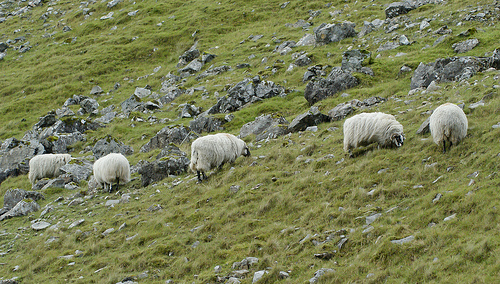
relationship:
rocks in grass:
[22, 18, 500, 181] [0, 0, 499, 282]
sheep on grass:
[25, 82, 475, 187] [0, 0, 499, 282]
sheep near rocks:
[25, 82, 475, 187] [22, 18, 500, 181]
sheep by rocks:
[25, 82, 475, 187] [22, 18, 500, 181]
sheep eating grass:
[25, 82, 475, 187] [0, 0, 499, 282]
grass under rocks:
[0, 0, 499, 282] [22, 18, 500, 181]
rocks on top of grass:
[22, 18, 500, 181] [0, 0, 499, 282]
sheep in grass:
[25, 82, 475, 187] [0, 0, 499, 282]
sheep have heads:
[25, 82, 475, 187] [229, 136, 409, 159]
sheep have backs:
[25, 82, 475, 187] [15, 120, 468, 166]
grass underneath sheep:
[0, 0, 499, 282] [25, 82, 475, 187]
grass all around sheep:
[0, 0, 499, 282] [25, 82, 475, 187]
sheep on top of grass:
[25, 82, 475, 187] [0, 0, 499, 282]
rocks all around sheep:
[22, 18, 500, 181] [25, 82, 475, 187]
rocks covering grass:
[22, 18, 500, 181] [0, 0, 499, 282]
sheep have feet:
[25, 82, 475, 187] [99, 176, 219, 192]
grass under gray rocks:
[0, 0, 499, 282] [22, 18, 500, 181]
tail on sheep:
[116, 147, 210, 173] [25, 82, 475, 187]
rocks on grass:
[22, 18, 500, 181] [0, 0, 499, 282]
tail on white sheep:
[116, 147, 210, 173] [25, 82, 475, 187]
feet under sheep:
[99, 176, 219, 192] [25, 82, 475, 187]